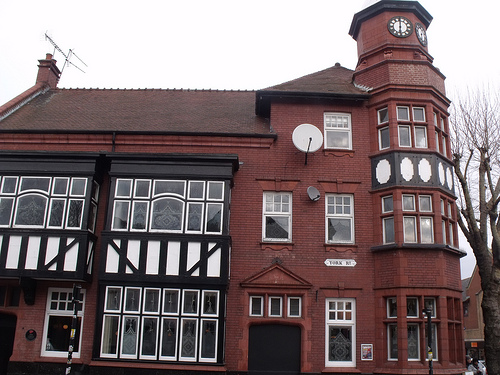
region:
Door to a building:
[315, 291, 361, 374]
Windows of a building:
[95, 277, 225, 372]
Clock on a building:
[380, 3, 415, 41]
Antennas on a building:
[21, 21, 86, 92]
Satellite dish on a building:
[286, 118, 326, 164]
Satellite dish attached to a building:
[296, 181, 326, 206]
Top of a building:
[80, 75, 283, 105]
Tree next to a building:
[450, 91, 496, 327]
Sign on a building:
[320, 251, 361, 276]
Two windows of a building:
[320, 107, 358, 254]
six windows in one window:
[321, 301, 364, 321]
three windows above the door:
[248, 301, 306, 363]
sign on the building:
[319, 253, 357, 271]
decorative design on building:
[365, 149, 463, 197]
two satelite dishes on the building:
[287, 117, 328, 212]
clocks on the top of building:
[390, 7, 447, 44]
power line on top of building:
[37, 32, 94, 90]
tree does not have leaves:
[447, 101, 497, 216]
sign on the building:
[356, 340, 374, 362]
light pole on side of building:
[417, 288, 463, 369]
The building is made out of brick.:
[239, 238, 383, 323]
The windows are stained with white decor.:
[121, 181, 221, 229]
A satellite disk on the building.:
[283, 103, 332, 183]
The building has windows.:
[98, 282, 223, 357]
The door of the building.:
[245, 311, 315, 371]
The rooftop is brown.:
[48, 81, 246, 133]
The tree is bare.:
[458, 138, 498, 296]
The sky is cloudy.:
[76, 33, 289, 87]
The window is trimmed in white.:
[323, 296, 363, 368]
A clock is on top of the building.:
[377, 13, 422, 45]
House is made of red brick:
[230, 123, 419, 358]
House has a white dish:
[289, 120, 326, 172]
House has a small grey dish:
[303, 177, 323, 211]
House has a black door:
[251, 322, 302, 372]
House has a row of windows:
[110, 173, 233, 205]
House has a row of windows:
[110, 200, 230, 231]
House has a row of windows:
[3, 177, 85, 195]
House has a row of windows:
[0, 198, 83, 228]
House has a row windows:
[103, 287, 229, 317]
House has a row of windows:
[101, 315, 221, 363]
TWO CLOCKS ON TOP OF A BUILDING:
[387, 16, 436, 50]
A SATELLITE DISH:
[279, 114, 336, 174]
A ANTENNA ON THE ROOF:
[38, 27, 91, 89]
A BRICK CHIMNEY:
[22, 44, 79, 95]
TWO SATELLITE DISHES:
[286, 120, 341, 207]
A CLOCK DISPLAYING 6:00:
[385, 7, 419, 40]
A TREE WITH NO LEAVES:
[445, 76, 497, 373]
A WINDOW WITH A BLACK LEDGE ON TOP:
[101, 148, 238, 235]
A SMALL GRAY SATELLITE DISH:
[301, 182, 327, 210]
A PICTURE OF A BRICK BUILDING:
[0, 0, 481, 370]